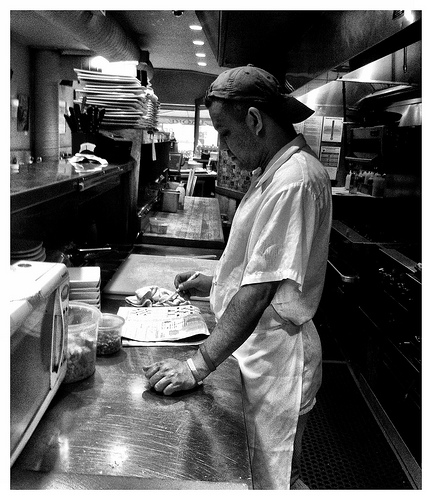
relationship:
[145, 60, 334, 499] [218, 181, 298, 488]
worker wearing apron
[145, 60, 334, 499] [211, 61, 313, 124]
worker wearing cap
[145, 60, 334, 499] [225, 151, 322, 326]
worker wearing shirt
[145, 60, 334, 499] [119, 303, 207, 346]
worker writing page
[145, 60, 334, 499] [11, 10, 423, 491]
worker in kitchen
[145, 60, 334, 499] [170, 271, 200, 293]
worker holding pen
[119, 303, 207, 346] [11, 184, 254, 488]
page on counter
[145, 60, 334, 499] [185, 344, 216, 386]
worker wearing wrist bands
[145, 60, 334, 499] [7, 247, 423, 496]
worker looking down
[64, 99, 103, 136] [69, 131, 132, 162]
knives in container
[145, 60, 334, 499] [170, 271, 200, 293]
worker has pen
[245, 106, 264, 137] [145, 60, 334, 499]
ear of worker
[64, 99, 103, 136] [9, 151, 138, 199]
knives on shelf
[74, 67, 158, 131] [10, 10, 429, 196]
plates in background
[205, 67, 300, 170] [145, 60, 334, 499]
head of worker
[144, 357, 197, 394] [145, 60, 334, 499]
hand of worker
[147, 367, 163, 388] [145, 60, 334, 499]
finger of worker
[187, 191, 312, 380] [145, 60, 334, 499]
arm of worker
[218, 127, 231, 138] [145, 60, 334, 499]
eye of worker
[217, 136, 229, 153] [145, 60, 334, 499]
nose of worker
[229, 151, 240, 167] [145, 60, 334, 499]
mouth of worker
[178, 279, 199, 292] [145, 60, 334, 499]
thumb of worker